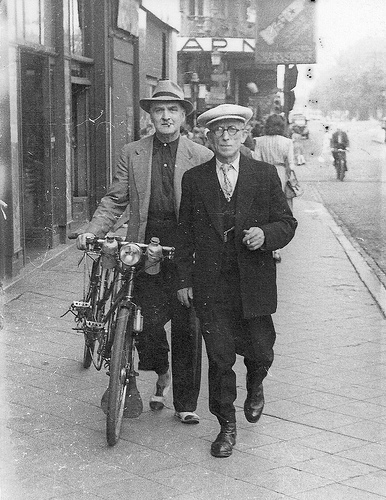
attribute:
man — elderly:
[173, 102, 295, 455]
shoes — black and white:
[176, 409, 199, 422]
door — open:
[15, 46, 53, 264]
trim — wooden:
[15, 42, 57, 270]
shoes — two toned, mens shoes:
[143, 369, 169, 409]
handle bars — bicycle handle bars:
[66, 227, 177, 272]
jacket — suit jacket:
[79, 133, 219, 243]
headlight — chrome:
[119, 240, 142, 267]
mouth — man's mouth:
[158, 120, 174, 127]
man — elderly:
[76, 80, 214, 425]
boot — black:
[212, 413, 237, 457]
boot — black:
[246, 373, 267, 417]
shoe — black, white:
[173, 407, 201, 426]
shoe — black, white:
[151, 376, 170, 411]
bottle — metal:
[144, 237, 163, 276]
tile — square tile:
[331, 380, 383, 404]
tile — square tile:
[290, 450, 382, 483]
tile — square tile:
[316, 353, 384, 375]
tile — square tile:
[291, 387, 356, 411]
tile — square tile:
[339, 417, 383, 443]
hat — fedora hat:
[138, 81, 194, 111]